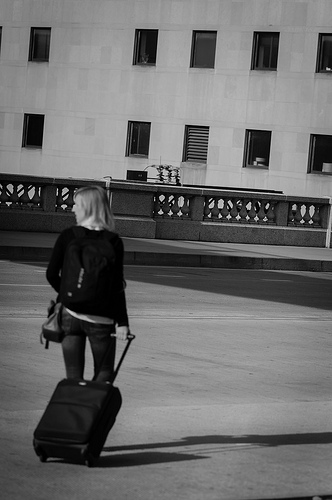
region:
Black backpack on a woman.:
[60, 227, 120, 308]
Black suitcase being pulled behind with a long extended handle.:
[33, 332, 134, 466]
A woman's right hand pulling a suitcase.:
[115, 322, 129, 340]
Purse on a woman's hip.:
[40, 299, 66, 342]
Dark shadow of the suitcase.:
[97, 448, 210, 467]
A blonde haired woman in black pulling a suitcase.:
[45, 184, 130, 386]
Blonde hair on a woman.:
[70, 184, 117, 230]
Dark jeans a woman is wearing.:
[58, 305, 116, 385]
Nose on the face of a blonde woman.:
[71, 204, 76, 212]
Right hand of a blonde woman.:
[115, 325, 128, 340]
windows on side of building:
[2, 5, 329, 170]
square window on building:
[250, 30, 279, 71]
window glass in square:
[191, 31, 217, 67]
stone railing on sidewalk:
[0, 173, 331, 248]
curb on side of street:
[0, 245, 331, 271]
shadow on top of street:
[2, 232, 331, 312]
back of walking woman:
[32, 185, 134, 468]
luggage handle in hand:
[32, 331, 134, 466]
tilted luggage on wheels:
[32, 377, 121, 467]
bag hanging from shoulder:
[41, 227, 77, 344]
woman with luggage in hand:
[30, 177, 142, 466]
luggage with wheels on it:
[25, 328, 139, 467]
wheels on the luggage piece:
[26, 441, 94, 466]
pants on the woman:
[58, 307, 117, 389]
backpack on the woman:
[63, 227, 116, 314]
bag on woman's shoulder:
[38, 282, 66, 344]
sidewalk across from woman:
[146, 236, 323, 255]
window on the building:
[242, 128, 273, 164]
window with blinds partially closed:
[186, 124, 206, 160]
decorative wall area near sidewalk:
[154, 184, 327, 240]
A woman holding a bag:
[45, 184, 133, 383]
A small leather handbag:
[39, 294, 62, 349]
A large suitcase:
[30, 334, 132, 464]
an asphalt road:
[0, 260, 328, 411]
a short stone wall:
[0, 171, 331, 249]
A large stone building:
[0, 0, 331, 225]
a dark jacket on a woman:
[46, 224, 137, 328]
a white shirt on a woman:
[63, 307, 117, 323]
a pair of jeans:
[56, 307, 112, 379]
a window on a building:
[240, 126, 271, 170]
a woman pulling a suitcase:
[38, 161, 171, 498]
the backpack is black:
[54, 232, 139, 323]